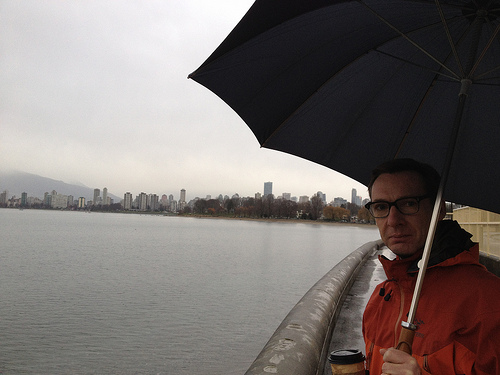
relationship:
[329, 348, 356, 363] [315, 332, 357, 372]
lid of cup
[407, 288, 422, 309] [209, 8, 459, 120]
pole of umbrella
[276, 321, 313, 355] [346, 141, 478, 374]
railing behind man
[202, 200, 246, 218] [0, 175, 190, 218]
trees in front of buildings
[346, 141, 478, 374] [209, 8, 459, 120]
man holding umbrella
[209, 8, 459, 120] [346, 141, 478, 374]
umbrella over man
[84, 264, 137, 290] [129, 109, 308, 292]
water of city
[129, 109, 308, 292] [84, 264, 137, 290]
city near water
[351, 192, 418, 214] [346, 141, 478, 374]
glasses of man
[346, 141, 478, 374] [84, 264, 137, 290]
man near water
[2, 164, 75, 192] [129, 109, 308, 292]
mountain near city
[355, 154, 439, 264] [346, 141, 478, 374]
head of man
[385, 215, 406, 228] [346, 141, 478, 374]
nose of man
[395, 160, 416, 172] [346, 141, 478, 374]
hair of man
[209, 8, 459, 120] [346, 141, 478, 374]
umbrella of man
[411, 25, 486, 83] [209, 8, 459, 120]
spokes of umbrella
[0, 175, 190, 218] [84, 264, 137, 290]
buildings behind water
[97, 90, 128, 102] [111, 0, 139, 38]
clouds in sky